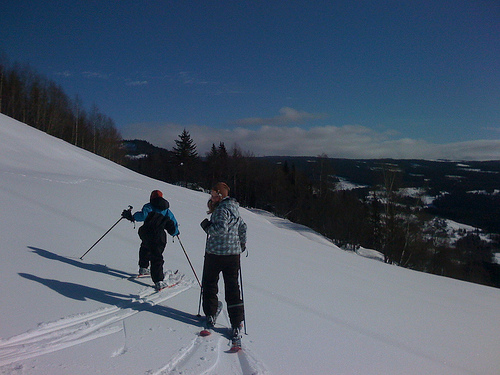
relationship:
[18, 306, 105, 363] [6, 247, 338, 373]
ski prints on snow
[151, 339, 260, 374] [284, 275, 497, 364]
prints in snow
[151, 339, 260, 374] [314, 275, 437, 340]
prints on snow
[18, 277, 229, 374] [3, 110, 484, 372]
ski prints on snow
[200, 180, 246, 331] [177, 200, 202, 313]
girl looking to her side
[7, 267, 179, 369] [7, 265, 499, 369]
ski trail in snow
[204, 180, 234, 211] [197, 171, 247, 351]
hat on girl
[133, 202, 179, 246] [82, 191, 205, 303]
jacket on boy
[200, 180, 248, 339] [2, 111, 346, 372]
girl on mountain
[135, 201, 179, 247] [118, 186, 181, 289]
jacket on skier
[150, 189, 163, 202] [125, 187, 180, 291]
hat on skier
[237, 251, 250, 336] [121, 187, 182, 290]
pole of boy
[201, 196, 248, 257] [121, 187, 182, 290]
jacket of boy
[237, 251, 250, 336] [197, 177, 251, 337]
pole of skier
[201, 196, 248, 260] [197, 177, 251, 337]
jacket of skier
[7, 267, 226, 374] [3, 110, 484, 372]
ski trail in snow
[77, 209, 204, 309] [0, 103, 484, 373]
ski trail in snow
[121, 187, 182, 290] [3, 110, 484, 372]
boy skiing on snow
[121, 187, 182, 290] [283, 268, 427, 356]
boy skiing in snow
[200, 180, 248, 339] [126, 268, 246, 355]
girl on skies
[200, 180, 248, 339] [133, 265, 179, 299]
girl standing on skis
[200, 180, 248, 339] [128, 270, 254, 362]
girl standing on skis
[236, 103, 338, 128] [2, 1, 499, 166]
cloud in sky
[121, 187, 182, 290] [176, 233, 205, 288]
boy holding ski pole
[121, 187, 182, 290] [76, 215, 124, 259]
boy holding ski pole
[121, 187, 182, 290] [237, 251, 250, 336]
boy holding pole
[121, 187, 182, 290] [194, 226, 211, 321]
boy holding pole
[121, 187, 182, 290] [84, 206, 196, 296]
boy holding ski poles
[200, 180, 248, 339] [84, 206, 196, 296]
girl holding ski poles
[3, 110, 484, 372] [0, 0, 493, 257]
snow covers ground